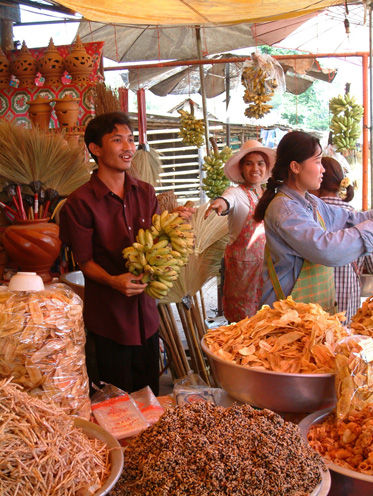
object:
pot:
[0, 217, 63, 284]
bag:
[92, 384, 167, 441]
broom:
[0, 118, 92, 220]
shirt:
[59, 167, 165, 345]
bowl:
[200, 321, 339, 413]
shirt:
[259, 183, 372, 313]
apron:
[222, 184, 268, 323]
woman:
[204, 139, 278, 323]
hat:
[223, 138, 277, 183]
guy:
[58, 110, 197, 404]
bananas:
[121, 207, 202, 297]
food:
[111, 397, 328, 495]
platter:
[302, 459, 335, 495]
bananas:
[240, 58, 279, 117]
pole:
[101, 51, 368, 71]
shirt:
[317, 192, 361, 325]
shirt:
[212, 182, 269, 250]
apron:
[262, 191, 337, 317]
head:
[238, 148, 270, 182]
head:
[83, 110, 136, 171]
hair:
[83, 111, 131, 165]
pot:
[62, 40, 95, 84]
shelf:
[2, 41, 104, 175]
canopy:
[49, 0, 358, 30]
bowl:
[8, 270, 45, 293]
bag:
[226, 52, 289, 124]